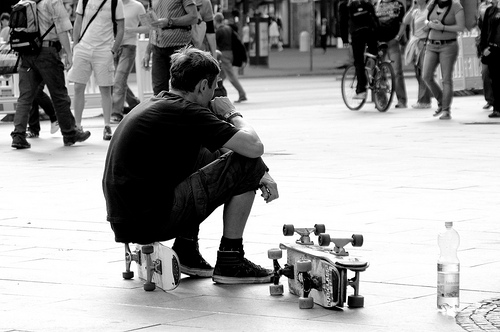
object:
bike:
[341, 40, 398, 113]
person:
[337, 0, 385, 95]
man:
[102, 45, 278, 288]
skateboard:
[121, 240, 181, 292]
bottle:
[434, 218, 464, 318]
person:
[6, 0, 90, 149]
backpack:
[5, 0, 56, 57]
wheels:
[350, 233, 365, 247]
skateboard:
[278, 223, 372, 269]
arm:
[194, 102, 264, 158]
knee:
[229, 147, 264, 181]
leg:
[177, 150, 262, 241]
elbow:
[245, 136, 264, 159]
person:
[62, 0, 126, 141]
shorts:
[64, 50, 117, 88]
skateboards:
[266, 249, 365, 312]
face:
[168, 46, 222, 107]